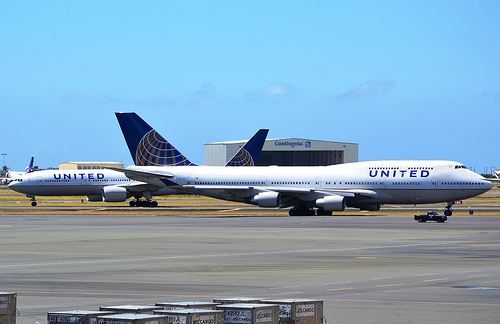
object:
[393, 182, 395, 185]
window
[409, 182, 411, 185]
window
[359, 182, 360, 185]
window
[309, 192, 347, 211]
jet engine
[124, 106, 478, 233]
plane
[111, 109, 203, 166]
tail wing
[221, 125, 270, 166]
tail wing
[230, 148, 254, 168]
globe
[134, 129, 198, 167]
globe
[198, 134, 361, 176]
hangar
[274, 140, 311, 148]
logo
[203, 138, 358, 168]
building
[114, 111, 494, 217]
plane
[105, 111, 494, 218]
airplane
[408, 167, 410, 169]
windows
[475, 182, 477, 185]
windows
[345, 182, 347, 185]
windows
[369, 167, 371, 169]
windows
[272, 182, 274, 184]
windows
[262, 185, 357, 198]
wing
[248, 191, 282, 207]
engine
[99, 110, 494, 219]
plane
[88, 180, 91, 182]
windows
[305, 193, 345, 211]
engine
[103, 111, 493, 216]
plane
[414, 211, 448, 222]
truck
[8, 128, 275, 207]
airplane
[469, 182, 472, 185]
window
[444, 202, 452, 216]
wheel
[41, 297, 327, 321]
carts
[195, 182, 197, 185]
windows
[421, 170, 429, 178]
letters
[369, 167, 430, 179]
logo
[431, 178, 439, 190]
door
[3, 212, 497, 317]
tarmac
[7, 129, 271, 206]
plane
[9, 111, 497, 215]
background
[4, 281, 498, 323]
foreground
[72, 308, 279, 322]
food